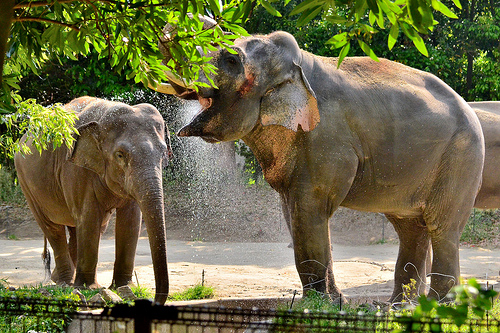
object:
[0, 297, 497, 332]
gate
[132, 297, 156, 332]
pole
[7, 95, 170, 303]
elephant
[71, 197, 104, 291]
leg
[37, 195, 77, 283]
legs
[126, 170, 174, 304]
trunk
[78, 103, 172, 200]
face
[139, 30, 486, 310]
elephant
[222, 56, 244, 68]
eye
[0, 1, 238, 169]
trees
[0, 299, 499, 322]
top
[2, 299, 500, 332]
fence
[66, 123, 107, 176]
ear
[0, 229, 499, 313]
floor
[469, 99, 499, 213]
elephant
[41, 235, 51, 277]
tail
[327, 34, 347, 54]
leaves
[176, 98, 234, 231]
water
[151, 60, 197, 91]
tusk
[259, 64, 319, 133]
ear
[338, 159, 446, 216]
stomach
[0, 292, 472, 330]
edge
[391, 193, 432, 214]
edge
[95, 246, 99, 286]
edge